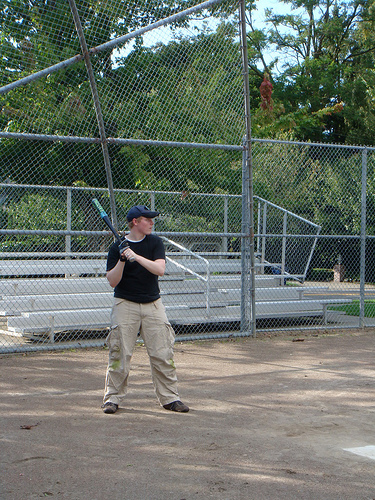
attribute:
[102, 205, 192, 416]
man — standing, wearing clothes, alone in the photo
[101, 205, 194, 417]
guy — playing baseball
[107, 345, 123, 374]
green stains — on pants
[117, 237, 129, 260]
batting glove — on one hand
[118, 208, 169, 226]
cap — navy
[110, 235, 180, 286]
shirt — black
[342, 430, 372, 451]
plate — home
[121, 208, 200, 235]
cap — blue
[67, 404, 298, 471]
shadow — falling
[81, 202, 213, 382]
man — holding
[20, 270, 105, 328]
steps — white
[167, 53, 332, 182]
trees — green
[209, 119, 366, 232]
fence — blue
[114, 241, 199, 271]
shirt — black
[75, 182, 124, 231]
bat — black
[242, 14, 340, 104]
sky — blue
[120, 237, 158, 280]
base — round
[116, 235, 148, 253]
collar — white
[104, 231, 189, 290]
shirt — black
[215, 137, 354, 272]
fence — chain link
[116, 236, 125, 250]
glove — worn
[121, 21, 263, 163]
fence — high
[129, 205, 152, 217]
baseball cap — blue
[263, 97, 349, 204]
foliage — green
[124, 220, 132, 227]
hair — brown